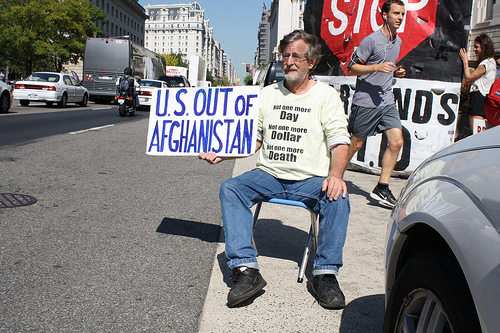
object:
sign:
[144, 85, 259, 157]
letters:
[148, 88, 259, 154]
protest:
[145, 28, 352, 310]